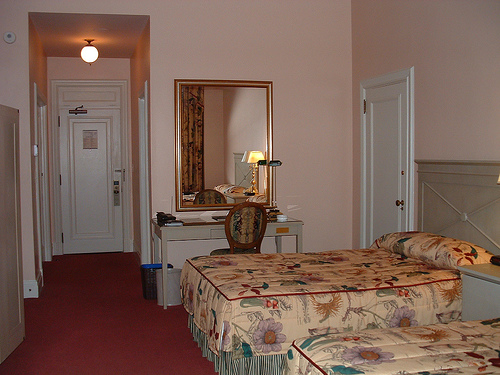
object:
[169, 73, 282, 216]
mirror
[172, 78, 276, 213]
frame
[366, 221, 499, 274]
pillow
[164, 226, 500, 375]
bed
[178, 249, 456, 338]
blanket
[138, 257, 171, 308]
garbage can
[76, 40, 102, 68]
light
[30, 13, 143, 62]
ceiling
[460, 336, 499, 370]
flower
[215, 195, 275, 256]
chair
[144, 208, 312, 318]
desk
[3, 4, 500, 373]
room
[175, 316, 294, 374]
skirt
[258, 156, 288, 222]
desk lamp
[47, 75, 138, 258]
mechanical door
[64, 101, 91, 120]
closer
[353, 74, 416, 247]
door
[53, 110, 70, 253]
gold hinges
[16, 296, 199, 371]
floor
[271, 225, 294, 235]
marking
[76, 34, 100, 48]
light fixture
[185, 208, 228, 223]
cosmetics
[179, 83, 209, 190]
drapes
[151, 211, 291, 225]
personal items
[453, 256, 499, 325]
nightstand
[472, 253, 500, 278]
personal items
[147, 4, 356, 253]
wall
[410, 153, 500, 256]
headboard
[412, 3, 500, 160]
wall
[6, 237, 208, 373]
carpet